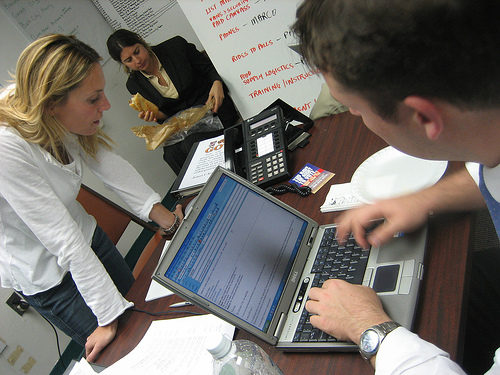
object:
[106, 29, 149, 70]
head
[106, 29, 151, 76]
hair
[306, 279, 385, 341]
hands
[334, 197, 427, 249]
hands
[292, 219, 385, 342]
keyboard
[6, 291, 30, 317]
electric outlet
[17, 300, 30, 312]
plug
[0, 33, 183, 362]
blonde woman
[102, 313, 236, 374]
paper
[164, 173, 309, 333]
email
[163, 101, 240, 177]
black pants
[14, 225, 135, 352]
black pants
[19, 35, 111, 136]
head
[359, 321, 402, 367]
watch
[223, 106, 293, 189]
phone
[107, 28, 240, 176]
employee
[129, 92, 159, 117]
burrito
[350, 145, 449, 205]
plate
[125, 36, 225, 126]
suit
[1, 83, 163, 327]
shirt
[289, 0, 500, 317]
planner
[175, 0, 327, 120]
writing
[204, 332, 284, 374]
bottle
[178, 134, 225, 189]
binder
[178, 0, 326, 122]
erase board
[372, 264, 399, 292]
touch pad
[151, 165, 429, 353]
computer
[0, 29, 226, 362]
woman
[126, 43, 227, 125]
jacket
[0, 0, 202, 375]
wall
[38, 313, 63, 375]
cord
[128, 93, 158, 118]
hoagie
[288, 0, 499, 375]
person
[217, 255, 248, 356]
open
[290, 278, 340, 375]
composed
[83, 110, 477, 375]
desk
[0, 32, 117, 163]
hair